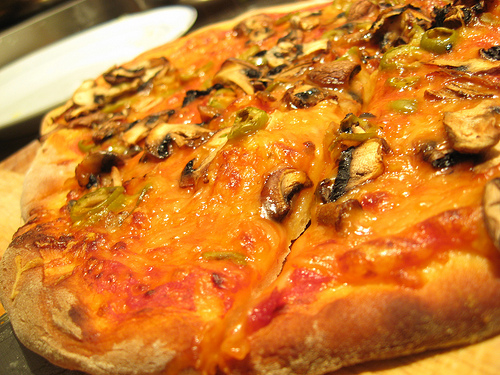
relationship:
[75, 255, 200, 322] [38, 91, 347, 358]
sauce under cheese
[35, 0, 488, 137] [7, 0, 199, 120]
pizza in background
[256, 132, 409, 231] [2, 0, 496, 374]
mushrooms on pizza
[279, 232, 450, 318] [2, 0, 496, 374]
tomato sauce on pizza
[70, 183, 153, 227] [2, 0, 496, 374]
pepper on pizza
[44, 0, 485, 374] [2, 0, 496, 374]
cheese on pizza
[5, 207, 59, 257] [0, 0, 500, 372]
crust on pizza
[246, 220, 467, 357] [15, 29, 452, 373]
crust on pizza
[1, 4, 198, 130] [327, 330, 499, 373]
plate on table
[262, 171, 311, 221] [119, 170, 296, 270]
mushroom on pizza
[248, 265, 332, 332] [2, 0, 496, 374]
sauce on pizza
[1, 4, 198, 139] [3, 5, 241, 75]
plate on counter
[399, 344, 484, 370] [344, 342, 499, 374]
surface of cuttingboard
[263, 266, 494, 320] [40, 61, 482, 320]
crust of pizza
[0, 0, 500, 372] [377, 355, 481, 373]
pizza on a wooden board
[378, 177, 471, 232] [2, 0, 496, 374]
cheese on pizza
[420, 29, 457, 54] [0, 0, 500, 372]
pepper on pizza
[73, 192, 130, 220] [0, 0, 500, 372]
pepper on pizza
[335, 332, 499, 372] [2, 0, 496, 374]
wood board under pizza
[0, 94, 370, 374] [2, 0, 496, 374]
slice of pizza